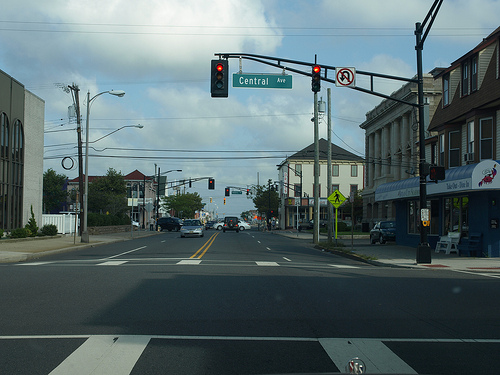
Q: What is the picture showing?
A: It is showing a town.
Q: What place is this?
A: It is a town.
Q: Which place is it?
A: It is a town.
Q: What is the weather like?
A: It is cloudy.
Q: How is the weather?
A: It is cloudy.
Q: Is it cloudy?
A: Yes, it is cloudy.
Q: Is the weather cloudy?
A: Yes, it is cloudy.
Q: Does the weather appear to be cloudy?
A: Yes, it is cloudy.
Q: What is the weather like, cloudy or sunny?
A: It is cloudy.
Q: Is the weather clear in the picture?
A: No, it is cloudy.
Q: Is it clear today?
A: No, it is cloudy.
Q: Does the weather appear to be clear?
A: No, it is cloudy.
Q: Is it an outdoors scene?
A: Yes, it is outdoors.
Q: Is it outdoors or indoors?
A: It is outdoors.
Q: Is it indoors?
A: No, it is outdoors.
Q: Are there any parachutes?
A: No, there are no parachutes.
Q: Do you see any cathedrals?
A: No, there are no cathedrals.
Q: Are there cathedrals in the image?
A: No, there are no cathedrals.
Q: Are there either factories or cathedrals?
A: No, there are no cathedrals or factories.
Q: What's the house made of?
A: The house is made of brick.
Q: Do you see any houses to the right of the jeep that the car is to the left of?
A: Yes, there is a house to the right of the jeep.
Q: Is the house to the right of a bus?
A: No, the house is to the right of the jeep.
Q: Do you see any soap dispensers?
A: No, there are no soap dispensers.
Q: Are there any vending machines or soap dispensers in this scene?
A: No, there are no soap dispensers or vending machines.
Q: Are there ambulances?
A: No, there are no ambulances.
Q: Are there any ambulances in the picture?
A: No, there are no ambulances.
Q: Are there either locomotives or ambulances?
A: No, there are no ambulances or locomotives.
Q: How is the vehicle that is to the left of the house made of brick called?
A: The vehicle is a car.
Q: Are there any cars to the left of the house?
A: Yes, there is a car to the left of the house.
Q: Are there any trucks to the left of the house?
A: No, there is a car to the left of the house.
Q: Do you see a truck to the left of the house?
A: No, there is a car to the left of the house.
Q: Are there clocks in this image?
A: No, there are no clocks.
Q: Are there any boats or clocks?
A: No, there are no clocks or boats.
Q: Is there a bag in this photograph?
A: No, there are no bags.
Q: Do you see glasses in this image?
A: No, there are no glasses.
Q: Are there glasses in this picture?
A: No, there are no glasses.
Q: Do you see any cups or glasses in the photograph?
A: No, there are no glasses or cups.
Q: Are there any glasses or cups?
A: No, there are no glasses or cups.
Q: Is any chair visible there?
A: Yes, there is a chair.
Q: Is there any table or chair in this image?
A: Yes, there is a chair.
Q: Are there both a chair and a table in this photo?
A: No, there is a chair but no tables.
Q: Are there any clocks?
A: No, there are no clocks.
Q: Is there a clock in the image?
A: No, there are no clocks.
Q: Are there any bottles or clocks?
A: No, there are no clocks or bottles.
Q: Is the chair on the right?
A: Yes, the chair is on the right of the image.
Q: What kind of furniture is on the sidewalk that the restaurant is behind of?
A: The piece of furniture is a chair.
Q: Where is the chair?
A: The chair is on the sidewalk.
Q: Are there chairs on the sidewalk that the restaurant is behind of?
A: Yes, there is a chair on the sidewalk.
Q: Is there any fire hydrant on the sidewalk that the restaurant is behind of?
A: No, there is a chair on the sidewalk.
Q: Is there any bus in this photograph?
A: No, there are no buses.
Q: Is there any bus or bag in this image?
A: No, there are no buses or bags.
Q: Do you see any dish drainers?
A: No, there are no dish drainers.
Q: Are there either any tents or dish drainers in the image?
A: No, there are no dish drainers or tents.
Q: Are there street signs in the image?
A: Yes, there is a street sign.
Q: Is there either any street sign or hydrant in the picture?
A: Yes, there is a street sign.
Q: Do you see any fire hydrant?
A: No, there are no fire hydrants.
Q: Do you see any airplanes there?
A: No, there are no airplanes.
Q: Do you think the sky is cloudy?
A: Yes, the sky is cloudy.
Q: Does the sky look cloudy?
A: Yes, the sky is cloudy.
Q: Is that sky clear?
A: No, the sky is cloudy.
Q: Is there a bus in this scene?
A: No, there are no buses.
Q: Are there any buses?
A: No, there are no buses.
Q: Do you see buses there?
A: No, there are no buses.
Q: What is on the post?
A: The sign is on the post.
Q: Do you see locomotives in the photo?
A: No, there are no locomotives.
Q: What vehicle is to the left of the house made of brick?
A: The vehicle is a car.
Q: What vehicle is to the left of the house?
A: The vehicle is a car.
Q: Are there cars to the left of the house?
A: Yes, there is a car to the left of the house.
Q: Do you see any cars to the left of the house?
A: Yes, there is a car to the left of the house.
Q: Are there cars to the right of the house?
A: No, the car is to the left of the house.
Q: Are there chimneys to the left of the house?
A: No, there is a car to the left of the house.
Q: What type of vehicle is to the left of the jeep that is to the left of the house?
A: The vehicle is a car.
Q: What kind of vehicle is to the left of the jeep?
A: The vehicle is a car.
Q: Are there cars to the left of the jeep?
A: Yes, there is a car to the left of the jeep.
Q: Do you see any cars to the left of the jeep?
A: Yes, there is a car to the left of the jeep.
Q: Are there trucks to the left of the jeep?
A: No, there is a car to the left of the jeep.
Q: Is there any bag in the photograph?
A: No, there are no bags.